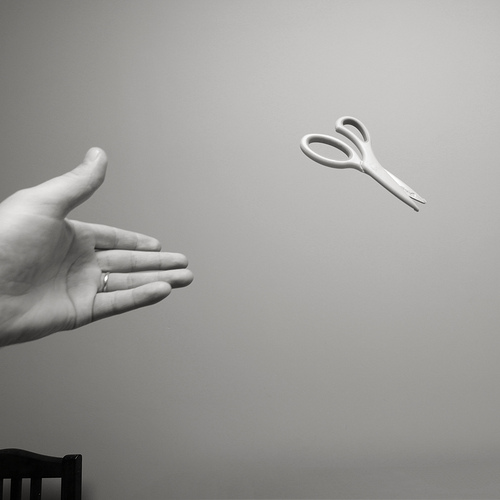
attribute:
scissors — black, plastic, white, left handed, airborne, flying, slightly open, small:
[298, 113, 428, 215]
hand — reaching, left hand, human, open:
[3, 145, 196, 351]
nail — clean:
[86, 146, 103, 170]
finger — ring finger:
[99, 269, 196, 290]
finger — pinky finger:
[96, 279, 172, 320]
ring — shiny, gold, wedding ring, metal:
[100, 271, 113, 292]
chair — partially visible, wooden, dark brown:
[0, 446, 84, 499]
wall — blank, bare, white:
[3, 4, 498, 499]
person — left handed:
[3, 141, 195, 363]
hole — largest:
[308, 138, 352, 165]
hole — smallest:
[343, 119, 370, 144]